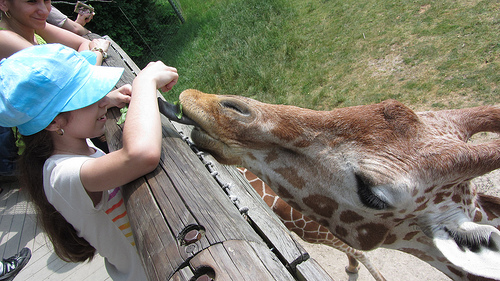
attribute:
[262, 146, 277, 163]
spot — rust colored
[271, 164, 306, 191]
spot — rust colored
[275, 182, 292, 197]
spot — rust colored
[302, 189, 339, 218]
spot — rust colored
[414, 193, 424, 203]
spot — rust colored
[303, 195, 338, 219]
spot — rust colored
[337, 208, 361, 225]
spot — rust colored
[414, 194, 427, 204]
spot — rust colored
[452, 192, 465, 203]
spot — rust colored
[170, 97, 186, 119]
leaf — small, green, thin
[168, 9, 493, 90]
grass — green 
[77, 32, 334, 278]
fence — wooden 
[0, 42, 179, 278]
girl — little 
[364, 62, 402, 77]
dirt — light brown, crumbly, small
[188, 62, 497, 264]
giraffe — hairy, white, light brown, two-horned, big black eyes, spotted, tall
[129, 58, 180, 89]
hand — pale pink, young, small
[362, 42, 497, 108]
grass — green 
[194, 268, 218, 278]
screw — metal, black, small, round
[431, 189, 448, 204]
spot — brown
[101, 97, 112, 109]
nose — small, young, pale pink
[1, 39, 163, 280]
girl — pale pink, young, caucasian, brunette, long hair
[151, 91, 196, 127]
tongue — black 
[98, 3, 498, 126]
green grass — shiny, sunlit, manicured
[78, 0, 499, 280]
exhibit — outdoors, fenced in, giraffe, people, green grass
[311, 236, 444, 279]
ground — dirt, light brown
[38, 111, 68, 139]
ear — small, young, pale pink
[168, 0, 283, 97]
grass — green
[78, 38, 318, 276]
railing — wooden 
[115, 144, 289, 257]
wood — small 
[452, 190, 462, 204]
spot — brown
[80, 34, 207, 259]
fence — metal, black, hard, thin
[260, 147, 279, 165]
spot — brown